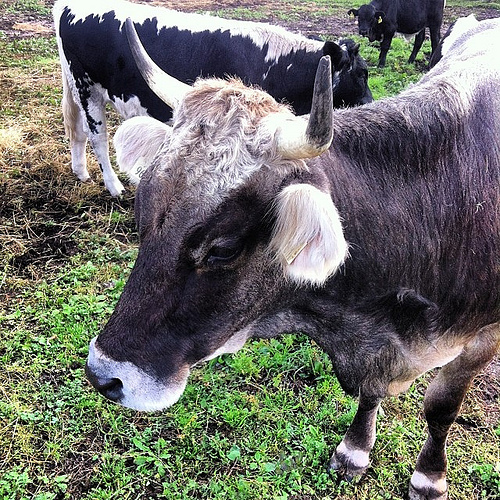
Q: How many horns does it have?
A: 2.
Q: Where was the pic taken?
A: In the field.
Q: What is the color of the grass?
A: Green.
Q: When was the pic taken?
A: During the day.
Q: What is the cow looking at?
A: The grass.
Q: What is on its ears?
A: A tag.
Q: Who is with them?
A: No one.